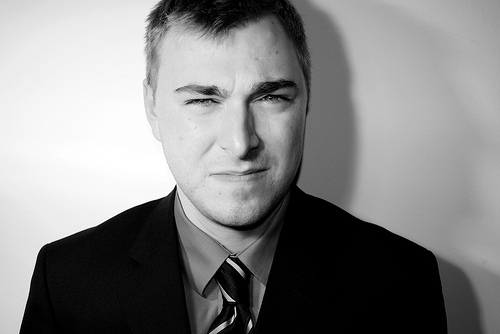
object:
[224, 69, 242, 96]
line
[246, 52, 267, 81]
line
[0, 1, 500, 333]
wall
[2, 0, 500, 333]
photograph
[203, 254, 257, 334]
tie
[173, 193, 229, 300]
collar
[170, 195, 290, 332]
shirt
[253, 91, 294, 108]
eyes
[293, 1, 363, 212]
shadow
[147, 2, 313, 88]
hair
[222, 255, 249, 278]
stripe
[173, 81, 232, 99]
eyebrows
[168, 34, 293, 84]
forehead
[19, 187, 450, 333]
jacket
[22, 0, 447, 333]
man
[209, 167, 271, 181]
mouth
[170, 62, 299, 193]
concerned look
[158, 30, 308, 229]
face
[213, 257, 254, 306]
knot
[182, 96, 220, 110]
eye